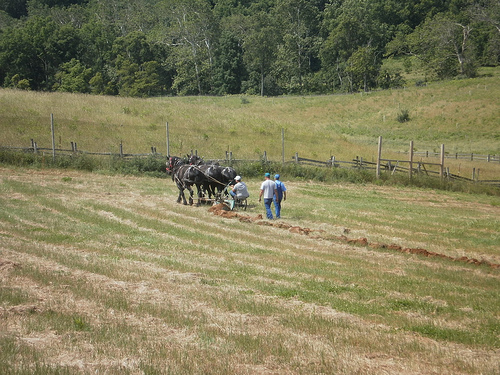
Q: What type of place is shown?
A: It is a field.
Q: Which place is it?
A: It is a field.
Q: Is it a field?
A: Yes, it is a field.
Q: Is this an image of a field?
A: Yes, it is showing a field.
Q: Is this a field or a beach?
A: It is a field.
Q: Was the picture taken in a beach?
A: No, the picture was taken in a field.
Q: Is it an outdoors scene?
A: Yes, it is outdoors.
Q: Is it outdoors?
A: Yes, it is outdoors.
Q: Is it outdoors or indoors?
A: It is outdoors.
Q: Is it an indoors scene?
A: No, it is outdoors.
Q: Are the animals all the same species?
A: Yes, all the animals are horses.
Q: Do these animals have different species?
A: No, all the animals are horses.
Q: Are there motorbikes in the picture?
A: No, there are no motorbikes.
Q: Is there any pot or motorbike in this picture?
A: No, there are no motorcycles or pots.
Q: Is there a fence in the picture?
A: Yes, there is a fence.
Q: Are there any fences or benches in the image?
A: Yes, there is a fence.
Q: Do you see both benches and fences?
A: No, there is a fence but no benches.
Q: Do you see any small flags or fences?
A: Yes, there is a small fence.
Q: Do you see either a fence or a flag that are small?
A: Yes, the fence is small.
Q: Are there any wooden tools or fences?
A: Yes, there is a wood fence.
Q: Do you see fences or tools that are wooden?
A: Yes, the fence is wooden.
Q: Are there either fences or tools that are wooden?
A: Yes, the fence is wooden.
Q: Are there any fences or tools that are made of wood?
A: Yes, the fence is made of wood.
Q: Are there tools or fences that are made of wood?
A: Yes, the fence is made of wood.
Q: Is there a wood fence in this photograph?
A: Yes, there is a wood fence.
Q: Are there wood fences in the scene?
A: Yes, there is a wood fence.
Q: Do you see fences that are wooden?
A: Yes, there is a fence that is wooden.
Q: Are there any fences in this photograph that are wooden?
A: Yes, there is a fence that is wooden.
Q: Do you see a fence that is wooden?
A: Yes, there is a fence that is wooden.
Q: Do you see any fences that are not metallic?
A: Yes, there is a wooden fence.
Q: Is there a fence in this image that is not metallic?
A: Yes, there is a wooden fence.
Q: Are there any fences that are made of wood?
A: Yes, there is a fence that is made of wood.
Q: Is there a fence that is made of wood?
A: Yes, there is a fence that is made of wood.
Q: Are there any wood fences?
A: Yes, there is a fence that is made of wood.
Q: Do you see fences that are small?
A: Yes, there is a small fence.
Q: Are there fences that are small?
A: Yes, there is a fence that is small.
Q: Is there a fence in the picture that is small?
A: Yes, there is a fence that is small.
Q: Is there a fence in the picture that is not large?
A: Yes, there is a small fence.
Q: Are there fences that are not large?
A: Yes, there is a small fence.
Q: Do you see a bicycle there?
A: No, there are no bicycles.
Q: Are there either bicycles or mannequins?
A: No, there are no bicycles or mannequins.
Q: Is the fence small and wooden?
A: Yes, the fence is small and wooden.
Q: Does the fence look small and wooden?
A: Yes, the fence is small and wooden.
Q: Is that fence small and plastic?
A: No, the fence is small but wooden.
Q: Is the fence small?
A: Yes, the fence is small.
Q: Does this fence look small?
A: Yes, the fence is small.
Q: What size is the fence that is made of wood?
A: The fence is small.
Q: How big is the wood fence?
A: The fence is small.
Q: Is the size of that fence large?
A: No, the fence is small.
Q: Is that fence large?
A: No, the fence is small.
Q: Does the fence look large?
A: No, the fence is small.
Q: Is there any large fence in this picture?
A: No, there is a fence but it is small.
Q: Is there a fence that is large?
A: No, there is a fence but it is small.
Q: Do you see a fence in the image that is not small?
A: No, there is a fence but it is small.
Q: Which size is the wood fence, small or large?
A: The fence is small.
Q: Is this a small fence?
A: Yes, this is a small fence.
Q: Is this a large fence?
A: No, this is a small fence.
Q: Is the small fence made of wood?
A: Yes, the fence is made of wood.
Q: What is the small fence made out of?
A: The fence is made of wood.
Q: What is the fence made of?
A: The fence is made of wood.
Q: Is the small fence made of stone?
A: No, the fence is made of wood.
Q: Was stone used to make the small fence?
A: No, the fence is made of wood.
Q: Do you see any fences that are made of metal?
A: No, there is a fence but it is made of wood.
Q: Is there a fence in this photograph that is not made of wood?
A: No, there is a fence but it is made of wood.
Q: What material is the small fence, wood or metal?
A: The fence is made of wood.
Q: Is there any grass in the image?
A: Yes, there is grass.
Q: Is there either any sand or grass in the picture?
A: Yes, there is grass.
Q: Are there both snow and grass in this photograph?
A: No, there is grass but no snow.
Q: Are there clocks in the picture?
A: No, there are no clocks.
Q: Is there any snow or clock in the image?
A: No, there are no clocks or snow.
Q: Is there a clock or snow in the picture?
A: No, there are no clocks or snow.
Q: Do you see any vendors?
A: No, there are no vendors.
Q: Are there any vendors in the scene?
A: No, there are no vendors.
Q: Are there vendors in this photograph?
A: No, there are no vendors.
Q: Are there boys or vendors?
A: No, there are no vendors or boys.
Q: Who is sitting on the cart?
A: The man is sitting on the cart.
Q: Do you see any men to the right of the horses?
A: Yes, there is a man to the right of the horses.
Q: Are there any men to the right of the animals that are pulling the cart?
A: Yes, there is a man to the right of the horses.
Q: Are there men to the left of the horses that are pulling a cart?
A: No, the man is to the right of the horses.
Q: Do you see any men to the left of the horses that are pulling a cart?
A: No, the man is to the right of the horses.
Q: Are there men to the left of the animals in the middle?
A: No, the man is to the right of the horses.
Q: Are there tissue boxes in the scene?
A: No, there are no tissue boxes.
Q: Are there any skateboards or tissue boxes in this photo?
A: No, there are no tissue boxes or skateboards.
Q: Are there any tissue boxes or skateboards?
A: No, there are no tissue boxes or skateboards.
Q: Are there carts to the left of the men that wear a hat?
A: Yes, there is a cart to the left of the men.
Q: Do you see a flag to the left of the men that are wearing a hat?
A: No, there is a cart to the left of the men.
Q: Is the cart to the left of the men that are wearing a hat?
A: Yes, the cart is to the left of the men.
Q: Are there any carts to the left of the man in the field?
A: Yes, there is a cart to the left of the man.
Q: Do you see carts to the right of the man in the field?
A: No, the cart is to the left of the man.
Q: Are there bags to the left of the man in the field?
A: No, there is a cart to the left of the man.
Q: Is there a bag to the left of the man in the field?
A: No, there is a cart to the left of the man.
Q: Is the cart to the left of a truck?
A: No, the cart is to the left of a man.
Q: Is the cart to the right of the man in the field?
A: No, the cart is to the left of the man.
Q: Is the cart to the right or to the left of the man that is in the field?
A: The cart is to the left of the man.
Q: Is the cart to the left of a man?
A: Yes, the cart is to the left of a man.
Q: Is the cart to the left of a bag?
A: No, the cart is to the left of a man.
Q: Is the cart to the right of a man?
A: No, the cart is to the left of a man.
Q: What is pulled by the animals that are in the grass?
A: The cart is pulled by the horses.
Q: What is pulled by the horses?
A: The cart is pulled by the horses.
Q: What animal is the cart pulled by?
A: The cart is pulled by the horses.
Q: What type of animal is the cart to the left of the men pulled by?
A: The cart is pulled by the horses.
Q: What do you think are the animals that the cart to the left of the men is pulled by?
A: The animals are horses.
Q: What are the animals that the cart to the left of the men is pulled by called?
A: The animals are horses.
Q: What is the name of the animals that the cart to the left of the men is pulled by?
A: The animals are horses.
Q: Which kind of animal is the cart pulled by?
A: The cart is pulled by the horses.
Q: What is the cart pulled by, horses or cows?
A: The cart is pulled by horses.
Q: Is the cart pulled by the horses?
A: Yes, the cart is pulled by the horses.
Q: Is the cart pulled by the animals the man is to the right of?
A: Yes, the cart is pulled by the horses.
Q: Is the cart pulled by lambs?
A: No, the cart is pulled by the horses.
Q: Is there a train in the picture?
A: No, there are no trains.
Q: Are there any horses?
A: Yes, there are horses.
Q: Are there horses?
A: Yes, there are horses.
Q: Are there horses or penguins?
A: Yes, there are horses.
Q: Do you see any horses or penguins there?
A: Yes, there are horses.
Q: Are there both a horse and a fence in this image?
A: Yes, there are both a horse and a fence.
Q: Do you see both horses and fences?
A: Yes, there are both horses and a fence.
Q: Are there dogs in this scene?
A: No, there are no dogs.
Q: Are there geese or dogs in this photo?
A: No, there are no dogs or geese.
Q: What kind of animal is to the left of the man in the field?
A: The animals are horses.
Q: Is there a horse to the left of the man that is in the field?
A: Yes, there are horses to the left of the man.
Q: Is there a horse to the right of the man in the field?
A: No, the horses are to the left of the man.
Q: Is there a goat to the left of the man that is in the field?
A: No, there are horses to the left of the man.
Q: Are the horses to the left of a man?
A: Yes, the horses are to the left of a man.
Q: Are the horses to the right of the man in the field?
A: No, the horses are to the left of the man.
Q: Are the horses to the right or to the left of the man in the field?
A: The horses are to the left of the man.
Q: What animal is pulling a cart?
A: The horses are pulling a cart.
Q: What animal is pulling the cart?
A: The horses are pulling a cart.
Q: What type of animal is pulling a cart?
A: The animals are horses.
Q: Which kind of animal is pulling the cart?
A: The animals are horses.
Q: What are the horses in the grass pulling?
A: The horses are pulling a cart.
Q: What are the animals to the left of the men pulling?
A: The horses are pulling a cart.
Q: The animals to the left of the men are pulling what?
A: The horses are pulling a cart.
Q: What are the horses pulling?
A: The horses are pulling a cart.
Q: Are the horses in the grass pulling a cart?
A: Yes, the horses are pulling a cart.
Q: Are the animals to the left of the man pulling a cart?
A: Yes, the horses are pulling a cart.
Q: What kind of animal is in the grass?
A: The animals are horses.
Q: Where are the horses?
A: The horses are in the grass.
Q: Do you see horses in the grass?
A: Yes, there are horses in the grass.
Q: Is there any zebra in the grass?
A: No, there are horses in the grass.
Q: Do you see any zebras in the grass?
A: No, there are horses in the grass.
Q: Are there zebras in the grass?
A: No, there are horses in the grass.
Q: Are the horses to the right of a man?
A: No, the horses are to the left of a man.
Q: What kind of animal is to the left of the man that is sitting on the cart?
A: The animals are horses.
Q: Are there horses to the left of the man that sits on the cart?
A: Yes, there are horses to the left of the man.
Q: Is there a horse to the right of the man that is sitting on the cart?
A: No, the horses are to the left of the man.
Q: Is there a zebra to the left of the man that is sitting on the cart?
A: No, there are horses to the left of the man.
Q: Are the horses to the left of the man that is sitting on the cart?
A: Yes, the horses are to the left of the man.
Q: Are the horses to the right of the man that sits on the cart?
A: No, the horses are to the left of the man.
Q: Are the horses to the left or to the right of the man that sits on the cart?
A: The horses are to the left of the man.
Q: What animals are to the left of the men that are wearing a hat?
A: The animals are horses.